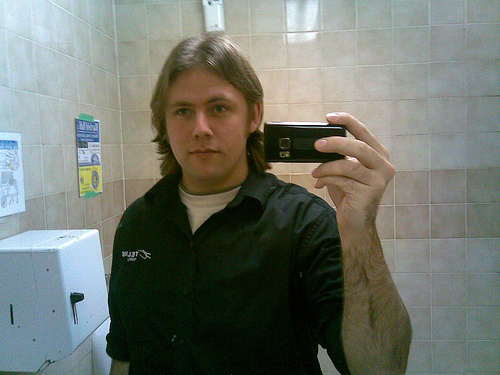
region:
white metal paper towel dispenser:
[5, 193, 139, 371]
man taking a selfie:
[94, 42, 424, 367]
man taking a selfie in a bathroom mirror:
[13, 19, 475, 370]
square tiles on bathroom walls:
[422, 150, 499, 280]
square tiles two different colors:
[404, 113, 496, 272]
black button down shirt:
[98, 177, 378, 371]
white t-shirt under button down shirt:
[150, 159, 267, 251]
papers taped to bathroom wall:
[8, 104, 126, 228]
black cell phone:
[255, 105, 362, 167]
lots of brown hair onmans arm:
[328, 233, 420, 365]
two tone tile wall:
[4, 3, 496, 373]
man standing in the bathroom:
[101, 32, 415, 371]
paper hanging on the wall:
[72, 115, 104, 197]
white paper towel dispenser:
[1, 226, 107, 373]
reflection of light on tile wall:
[280, 0, 324, 45]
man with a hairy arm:
[106, 34, 415, 372]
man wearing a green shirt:
[103, 34, 413, 371]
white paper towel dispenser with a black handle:
[0, 226, 107, 373]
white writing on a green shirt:
[113, 246, 155, 261]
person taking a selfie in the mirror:
[88, 21, 431, 364]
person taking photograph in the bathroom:
[11, 24, 457, 351]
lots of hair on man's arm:
[342, 226, 409, 365]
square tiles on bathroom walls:
[397, 35, 482, 259]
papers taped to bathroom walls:
[5, 99, 119, 226]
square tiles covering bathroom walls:
[409, 106, 490, 255]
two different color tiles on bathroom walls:
[415, 129, 497, 271]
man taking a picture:
[83, 36, 430, 370]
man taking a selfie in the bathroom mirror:
[91, 30, 426, 366]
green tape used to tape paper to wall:
[79, 104, 98, 124]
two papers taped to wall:
[4, 98, 111, 222]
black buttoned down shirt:
[85, 165, 369, 370]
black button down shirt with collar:
[92, 169, 359, 367]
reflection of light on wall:
[274, 3, 336, 50]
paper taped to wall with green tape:
[65, 108, 112, 207]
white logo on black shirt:
[104, 228, 166, 285]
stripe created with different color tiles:
[422, 118, 498, 250]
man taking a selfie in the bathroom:
[87, 28, 387, 365]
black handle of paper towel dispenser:
[55, 281, 97, 313]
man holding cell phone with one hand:
[242, 63, 441, 216]